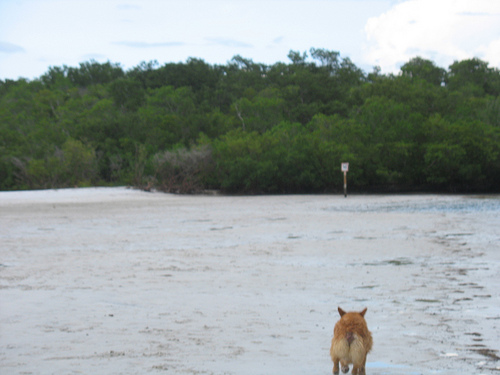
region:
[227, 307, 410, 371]
a dog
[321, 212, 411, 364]
a dog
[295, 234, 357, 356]
a dog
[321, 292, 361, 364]
a dog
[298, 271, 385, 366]
a dog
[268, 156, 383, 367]
a dog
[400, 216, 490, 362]
water waves flowing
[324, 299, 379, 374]
a small dog in water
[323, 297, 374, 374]
brown and white fur on animal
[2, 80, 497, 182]
tress in background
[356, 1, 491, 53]
clouds in the sky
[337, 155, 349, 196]
a sign on a post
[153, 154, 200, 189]
dead limbs off bushes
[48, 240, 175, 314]
water is faded color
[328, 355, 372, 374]
four legs on dog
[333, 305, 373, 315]
two ears on dog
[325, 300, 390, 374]
the fox is red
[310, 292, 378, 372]
the fox is on the beach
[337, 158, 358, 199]
the sign is white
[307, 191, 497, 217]
the water is sparkling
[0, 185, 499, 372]
the beach is sandy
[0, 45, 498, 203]
the trees are green and leafy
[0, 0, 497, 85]
the sky is cloudy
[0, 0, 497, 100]
the sky is hazy and light blue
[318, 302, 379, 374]
the fox is running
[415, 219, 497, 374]
the sand has footprints in it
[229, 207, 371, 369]
a golden dog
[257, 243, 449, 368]
a golden dog with his ears up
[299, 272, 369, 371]
a golden dog in front of the water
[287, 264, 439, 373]
a dog in front of the water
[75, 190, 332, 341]
a body of water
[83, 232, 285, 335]
a body of calm water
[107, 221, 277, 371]
a body of water that is calm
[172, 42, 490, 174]
green leaves on a tree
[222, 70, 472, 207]
trees with geen leaves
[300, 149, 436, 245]
a sign in the water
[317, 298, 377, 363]
a dog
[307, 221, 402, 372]
a dog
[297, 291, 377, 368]
a dog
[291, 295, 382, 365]
a dog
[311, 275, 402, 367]
a dog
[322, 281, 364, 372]
a dog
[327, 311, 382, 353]
a dog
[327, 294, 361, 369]
a dog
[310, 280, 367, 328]
a dog